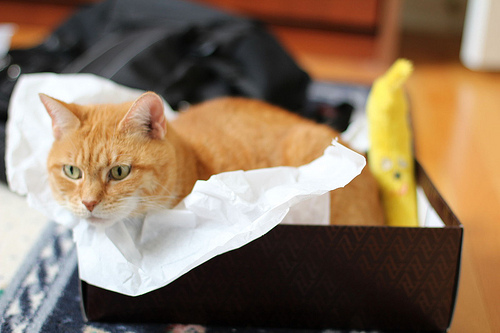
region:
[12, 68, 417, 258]
A yellow cat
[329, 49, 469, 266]
A banana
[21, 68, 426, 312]
A cat in a box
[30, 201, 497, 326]
The box is brown.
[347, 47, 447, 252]
The banana is yellow.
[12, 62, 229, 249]
The cat has green eyes.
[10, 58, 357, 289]
Tissue paper in the box.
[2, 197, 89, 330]
A white rug with blue trim.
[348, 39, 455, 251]
The banana has a sticker on it.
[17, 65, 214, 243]
The cat is looking at something in the distance.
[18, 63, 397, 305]
An orange cat in a box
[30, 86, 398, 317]
An orange cat in a black box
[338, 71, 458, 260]
A banana in a box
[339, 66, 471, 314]
A banana in a black box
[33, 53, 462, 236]
An orange cat next to a banana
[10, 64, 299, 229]
An orange cat on white paper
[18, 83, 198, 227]
The head of a cat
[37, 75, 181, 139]
The ears of a cat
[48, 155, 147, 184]
The eyes of a cat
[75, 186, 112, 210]
The nose of a cat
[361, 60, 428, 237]
banana is yellow with eyes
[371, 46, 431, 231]
A yellow banana standing upright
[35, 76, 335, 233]
an orange striped tabby cat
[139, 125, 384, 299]
a portion of white napkin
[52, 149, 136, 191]
light yellowish cat eyes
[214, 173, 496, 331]
a dark brown shoe box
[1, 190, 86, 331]
a white and dark grey carpet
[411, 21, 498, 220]
light hardwood flooring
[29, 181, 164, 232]
a pink nose separates white whiskers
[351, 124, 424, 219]
a smiling face on a toy banana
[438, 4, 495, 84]
the bottom corner of a white door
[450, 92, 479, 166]
clear shine on floor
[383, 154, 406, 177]
label on yellow banana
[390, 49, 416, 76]
tip of the banana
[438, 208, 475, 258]
small crack in shoe box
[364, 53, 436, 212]
large yellow banana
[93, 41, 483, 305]
large black box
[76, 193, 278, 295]
crinkled white paper in box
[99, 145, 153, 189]
beautiful green cat eyes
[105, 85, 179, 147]
white whiskers in cat's ear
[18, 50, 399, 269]
beautiful cat in box